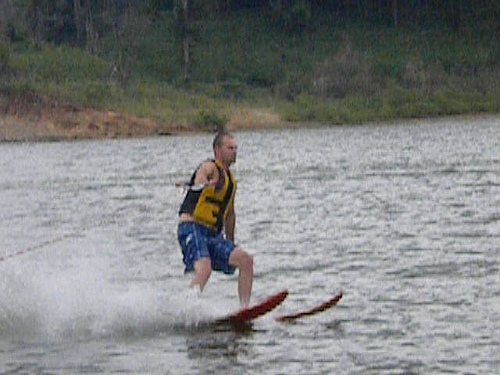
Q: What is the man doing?
A: Water skiing.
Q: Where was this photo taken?
A: A lake.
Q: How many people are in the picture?
A: 1.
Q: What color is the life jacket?
A: Yellow.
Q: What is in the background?
A: A river bank.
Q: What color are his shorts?
A: Blue.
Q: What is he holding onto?
A: A rope.